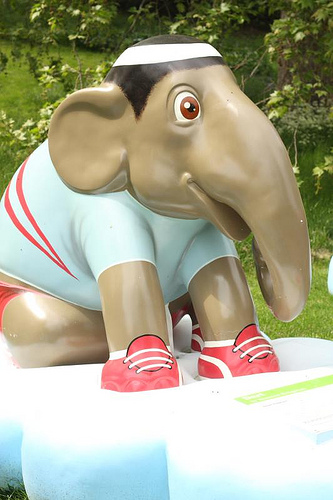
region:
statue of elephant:
[2, 28, 313, 394]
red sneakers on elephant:
[97, 330, 185, 393]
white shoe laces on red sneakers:
[117, 344, 177, 375]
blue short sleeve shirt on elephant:
[0, 123, 241, 311]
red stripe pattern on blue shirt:
[0, 151, 84, 295]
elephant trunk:
[214, 168, 323, 327]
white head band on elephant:
[110, 42, 223, 67]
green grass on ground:
[243, 254, 331, 339]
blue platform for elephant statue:
[2, 329, 331, 496]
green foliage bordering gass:
[60, 1, 329, 167]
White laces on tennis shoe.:
[233, 338, 271, 366]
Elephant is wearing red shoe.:
[201, 336, 284, 373]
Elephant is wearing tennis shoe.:
[123, 352, 177, 404]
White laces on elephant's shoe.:
[127, 345, 179, 386]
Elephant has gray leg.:
[115, 278, 157, 338]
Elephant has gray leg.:
[205, 277, 231, 315]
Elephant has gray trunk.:
[259, 233, 299, 287]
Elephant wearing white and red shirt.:
[17, 190, 86, 262]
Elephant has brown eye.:
[177, 96, 192, 114]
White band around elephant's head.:
[114, 32, 233, 70]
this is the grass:
[8, 81, 34, 100]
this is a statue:
[11, 50, 317, 497]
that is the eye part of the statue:
[174, 97, 199, 126]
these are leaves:
[272, 12, 330, 134]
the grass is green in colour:
[3, 83, 33, 106]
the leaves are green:
[278, 9, 328, 135]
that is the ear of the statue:
[64, 92, 136, 185]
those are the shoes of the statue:
[104, 337, 187, 387]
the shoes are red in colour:
[121, 353, 176, 396]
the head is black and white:
[124, 46, 230, 81]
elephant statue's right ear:
[47, 85, 129, 197]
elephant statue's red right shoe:
[100, 334, 183, 391]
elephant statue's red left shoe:
[196, 322, 279, 378]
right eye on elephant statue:
[165, 82, 202, 128]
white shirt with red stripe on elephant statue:
[0, 135, 241, 312]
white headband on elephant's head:
[112, 43, 223, 68]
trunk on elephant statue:
[195, 82, 312, 322]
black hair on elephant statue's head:
[102, 33, 228, 121]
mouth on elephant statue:
[182, 170, 251, 242]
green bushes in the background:
[2, 0, 332, 195]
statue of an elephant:
[0, 26, 328, 402]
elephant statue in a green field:
[4, 5, 326, 414]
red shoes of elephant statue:
[95, 325, 279, 395]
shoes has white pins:
[98, 326, 286, 394]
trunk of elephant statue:
[219, 124, 324, 332]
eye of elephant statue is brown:
[165, 79, 207, 135]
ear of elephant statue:
[40, 81, 129, 202]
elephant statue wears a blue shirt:
[0, 25, 324, 403]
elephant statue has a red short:
[0, 257, 84, 363]